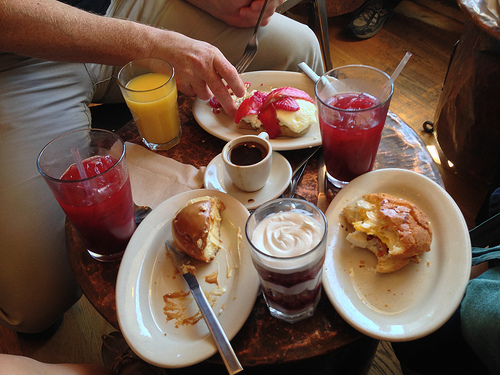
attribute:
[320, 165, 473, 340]
plate — white, oval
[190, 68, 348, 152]
plate — white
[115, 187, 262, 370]
plate — white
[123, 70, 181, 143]
juice — orange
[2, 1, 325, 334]
pants — tan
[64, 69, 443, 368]
table — small, round, wooden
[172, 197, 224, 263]
doughnut — eaten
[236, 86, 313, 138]
strawberries — sliced, red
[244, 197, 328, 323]
milkshake — vanilla, chocolate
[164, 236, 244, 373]
knife — silver, dirty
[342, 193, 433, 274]
sandwich — eaten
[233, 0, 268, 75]
fork — silver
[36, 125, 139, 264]
glass — tall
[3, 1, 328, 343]
man — eating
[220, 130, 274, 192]
cup — small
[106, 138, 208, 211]
napkin — white, brown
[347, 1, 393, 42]
shoe — grey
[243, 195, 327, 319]
glass — clear